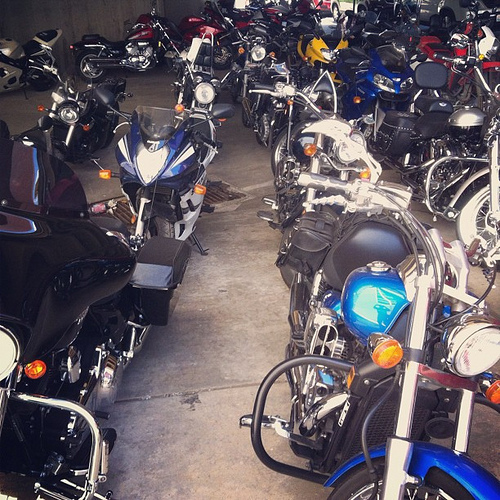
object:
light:
[337, 129, 368, 165]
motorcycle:
[219, 16, 304, 129]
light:
[319, 48, 340, 62]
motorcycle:
[70, 7, 185, 83]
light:
[193, 82, 216, 105]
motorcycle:
[27, 58, 124, 164]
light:
[57, 103, 82, 125]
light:
[250, 44, 266, 61]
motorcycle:
[251, 170, 500, 458]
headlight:
[335, 129, 367, 165]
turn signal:
[98, 169, 111, 179]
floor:
[225, 130, 252, 165]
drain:
[112, 180, 248, 226]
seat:
[81, 34, 129, 57]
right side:
[341, 74, 383, 122]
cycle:
[94, 88, 237, 257]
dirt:
[214, 236, 245, 282]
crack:
[244, 174, 262, 195]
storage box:
[376, 110, 419, 157]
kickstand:
[190, 232, 209, 255]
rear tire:
[76, 49, 110, 84]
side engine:
[433, 141, 462, 171]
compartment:
[126, 26, 155, 41]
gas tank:
[153, 202, 168, 217]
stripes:
[335, 47, 416, 122]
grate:
[200, 204, 215, 215]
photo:
[0, 0, 500, 500]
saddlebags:
[414, 61, 455, 115]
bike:
[0, 26, 61, 93]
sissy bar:
[297, 132, 354, 211]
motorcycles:
[166, 30, 240, 111]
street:
[228, 141, 258, 174]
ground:
[135, 77, 169, 103]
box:
[276, 211, 336, 278]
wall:
[0, 0, 205, 79]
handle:
[249, 89, 287, 98]